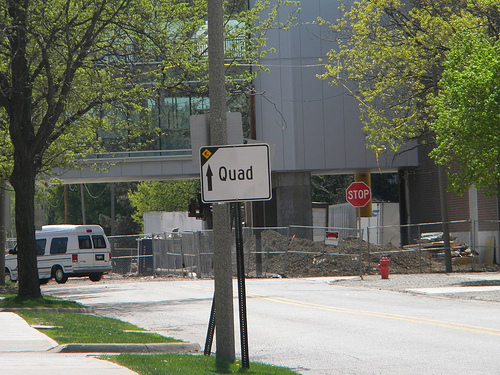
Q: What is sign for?
A: Directional sign.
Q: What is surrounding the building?
A: Chain link fence.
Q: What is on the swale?
A: Green tree.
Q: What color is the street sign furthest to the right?
A: Red.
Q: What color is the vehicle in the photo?
A: White.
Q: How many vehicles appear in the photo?
A: One.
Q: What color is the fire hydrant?
A: Red.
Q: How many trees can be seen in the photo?
A: Three.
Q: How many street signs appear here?
A: Three.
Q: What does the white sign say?
A: Quad.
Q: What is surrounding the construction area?
A: Chain link fence.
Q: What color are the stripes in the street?
A: Yellow.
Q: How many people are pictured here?
A: Zero.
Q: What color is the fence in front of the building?
A: Gray.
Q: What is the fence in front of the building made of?
A: Metal.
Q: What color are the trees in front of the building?
A: Green.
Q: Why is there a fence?
A: Preventing people from getting into the construction area.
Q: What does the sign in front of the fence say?
A: Stop.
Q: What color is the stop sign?
A: Red.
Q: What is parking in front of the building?
A: A van.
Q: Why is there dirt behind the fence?
A: They're doing construction.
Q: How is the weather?
A: It is sunny.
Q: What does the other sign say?
A: It says stop.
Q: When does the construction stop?
A: Late afternoon.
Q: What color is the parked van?
A: It is white.